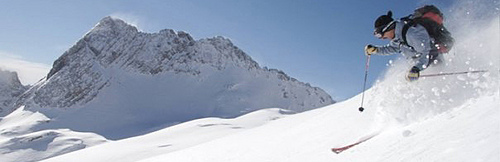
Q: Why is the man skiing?
A: Fun.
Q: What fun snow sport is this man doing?
A: Skiing.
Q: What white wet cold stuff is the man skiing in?
A: Snow.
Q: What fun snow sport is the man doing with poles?
A: Skiing.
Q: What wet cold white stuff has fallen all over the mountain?
A: Snow.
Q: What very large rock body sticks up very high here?
A: Mountain.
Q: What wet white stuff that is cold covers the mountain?
A: Snow.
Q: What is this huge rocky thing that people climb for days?
A: Mountain.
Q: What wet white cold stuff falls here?
A: Snow.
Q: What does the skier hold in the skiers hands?
A: Ski poles.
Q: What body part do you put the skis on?
A: Feet.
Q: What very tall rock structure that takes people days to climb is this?
A: Mountain.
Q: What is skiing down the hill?
A: The skier.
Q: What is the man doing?
A: Skiing.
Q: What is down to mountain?
A: Skiing.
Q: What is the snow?
A: Fresh.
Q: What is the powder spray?
A: Fresh snow.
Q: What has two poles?
A: The skier.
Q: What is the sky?
A: Clear.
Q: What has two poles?
A: The skier.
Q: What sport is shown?
A: Skiing.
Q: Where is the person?
A: On a ski slope.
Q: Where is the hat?
A: On the person's head.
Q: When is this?
A: Daytime.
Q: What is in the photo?
A: Snow.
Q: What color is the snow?
A: White.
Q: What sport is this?
A: Skiing.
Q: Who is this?
A: Man.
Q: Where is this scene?
A: On a ski slope.